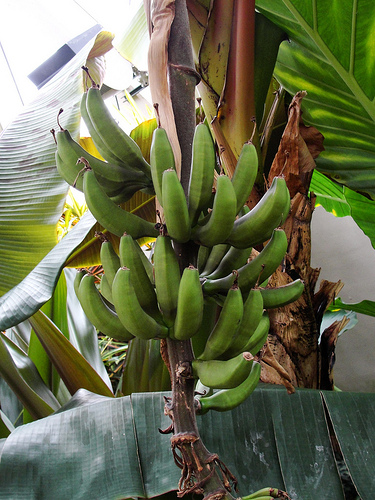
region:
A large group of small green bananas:
[46, 79, 294, 412]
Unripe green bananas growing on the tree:
[38, 81, 309, 416]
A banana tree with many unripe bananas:
[77, 0, 338, 496]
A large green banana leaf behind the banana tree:
[13, 385, 371, 499]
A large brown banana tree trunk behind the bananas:
[215, 95, 350, 399]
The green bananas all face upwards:
[59, 75, 293, 410]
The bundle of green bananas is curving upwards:
[70, 231, 208, 346]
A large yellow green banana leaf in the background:
[0, 25, 116, 297]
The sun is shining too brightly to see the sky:
[0, 0, 62, 49]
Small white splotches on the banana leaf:
[241, 426, 275, 470]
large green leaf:
[254, 1, 374, 198]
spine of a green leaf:
[282, 1, 373, 125]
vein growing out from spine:
[348, 0, 359, 72]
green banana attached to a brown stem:
[190, 351, 253, 386]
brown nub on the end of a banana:
[242, 351, 252, 359]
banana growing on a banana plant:
[111, 267, 170, 339]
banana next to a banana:
[87, 85, 150, 176]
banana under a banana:
[160, 167, 191, 243]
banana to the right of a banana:
[195, 268, 245, 359]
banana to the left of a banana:
[148, 126, 178, 210]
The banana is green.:
[78, 59, 153, 173]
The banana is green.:
[46, 113, 149, 190]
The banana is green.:
[75, 158, 158, 243]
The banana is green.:
[107, 263, 171, 348]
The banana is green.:
[76, 272, 136, 346]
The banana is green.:
[172, 262, 205, 348]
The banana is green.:
[151, 222, 184, 332]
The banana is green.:
[159, 160, 195, 250]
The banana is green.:
[186, 114, 217, 235]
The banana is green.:
[192, 164, 239, 248]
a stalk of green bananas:
[48, 62, 305, 498]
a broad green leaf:
[253, 1, 374, 204]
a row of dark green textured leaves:
[1, 390, 372, 497]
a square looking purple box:
[25, 22, 103, 91]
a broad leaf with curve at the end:
[0, 30, 127, 295]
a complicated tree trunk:
[184, 0, 351, 390]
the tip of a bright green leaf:
[327, 297, 373, 318]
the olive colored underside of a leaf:
[23, 308, 117, 400]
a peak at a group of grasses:
[95, 331, 135, 393]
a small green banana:
[111, 265, 169, 339]